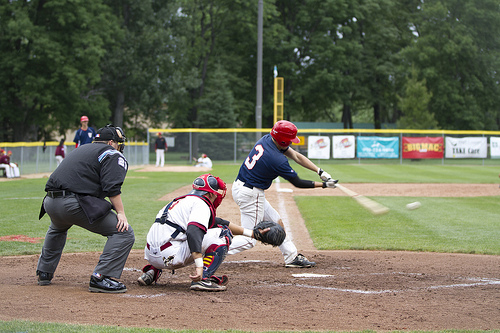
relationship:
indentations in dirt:
[85, 294, 116, 304] [298, 277, 485, 320]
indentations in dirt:
[129, 308, 166, 319] [298, 277, 485, 320]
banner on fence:
[339, 135, 429, 161] [88, 128, 488, 164]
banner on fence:
[401, 137, 442, 161] [142, 125, 498, 159]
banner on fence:
[445, 135, 488, 162] [142, 125, 498, 159]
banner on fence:
[354, 136, 402, 159] [142, 125, 498, 159]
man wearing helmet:
[225, 120, 340, 269] [270, 122, 299, 151]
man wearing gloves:
[225, 120, 340, 269] [315, 168, 340, 187]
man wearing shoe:
[225, 120, 340, 269] [289, 249, 318, 274]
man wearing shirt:
[207, 120, 339, 271] [233, 129, 319, 193]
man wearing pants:
[37, 126, 131, 297] [36, 190, 135, 280]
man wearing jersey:
[225, 120, 340, 269] [237, 135, 296, 190]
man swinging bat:
[225, 120, 340, 269] [332, 182, 389, 224]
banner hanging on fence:
[354, 136, 402, 159] [4, 125, 499, 169]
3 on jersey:
[244, 141, 264, 166] [245, 130, 295, 193]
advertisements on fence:
[309, 134, 490, 163] [173, 132, 498, 164]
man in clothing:
[37, 126, 132, 294] [43, 140, 130, 267]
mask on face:
[212, 177, 228, 207] [188, 171, 227, 204]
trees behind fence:
[3, 6, 245, 131] [0, 126, 225, 170]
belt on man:
[43, 182, 75, 199] [37, 126, 132, 294]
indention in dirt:
[235, 290, 293, 312] [2, 245, 498, 330]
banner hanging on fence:
[401, 137, 442, 161] [151, 125, 497, 162]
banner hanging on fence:
[331, 135, 356, 160] [151, 125, 497, 162]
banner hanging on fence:
[401, 137, 428, 161] [145, 124, 484, 164]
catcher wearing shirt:
[138, 173, 272, 291] [142, 192, 213, 247]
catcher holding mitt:
[138, 173, 270, 303] [248, 212, 289, 247]